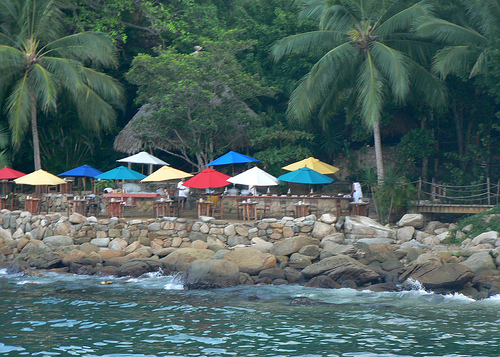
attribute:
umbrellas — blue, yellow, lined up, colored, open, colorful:
[179, 146, 341, 196]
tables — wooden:
[33, 190, 348, 210]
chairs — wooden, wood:
[25, 193, 267, 223]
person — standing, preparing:
[348, 179, 363, 202]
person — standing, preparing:
[175, 178, 191, 204]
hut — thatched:
[325, 131, 415, 196]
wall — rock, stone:
[360, 150, 410, 183]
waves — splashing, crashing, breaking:
[44, 262, 183, 297]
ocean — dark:
[4, 269, 499, 354]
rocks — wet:
[6, 231, 491, 298]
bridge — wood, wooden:
[401, 177, 495, 214]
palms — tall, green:
[1, 5, 496, 136]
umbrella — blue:
[272, 165, 332, 190]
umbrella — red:
[178, 163, 235, 192]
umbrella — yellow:
[137, 160, 200, 183]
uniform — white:
[353, 180, 362, 198]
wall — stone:
[1, 211, 474, 277]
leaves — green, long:
[43, 22, 124, 130]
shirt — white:
[171, 182, 191, 195]